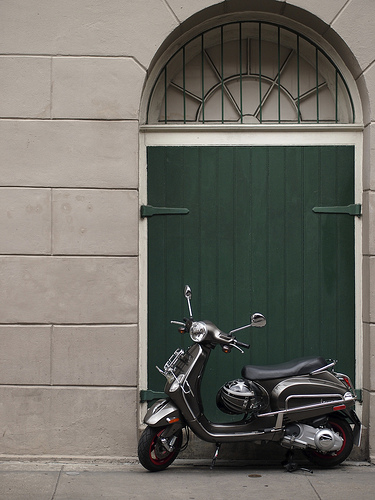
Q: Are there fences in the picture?
A: No, there are no fences.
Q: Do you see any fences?
A: No, there are no fences.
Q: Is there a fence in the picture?
A: No, there are no fences.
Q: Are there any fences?
A: No, there are no fences.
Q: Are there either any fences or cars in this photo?
A: No, there are no fences or cars.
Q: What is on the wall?
A: The bricks are on the wall.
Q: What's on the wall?
A: The bricks are on the wall.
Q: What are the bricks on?
A: The bricks are on the wall.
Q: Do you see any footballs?
A: No, there are no footballs.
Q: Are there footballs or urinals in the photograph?
A: No, there are no footballs or urinals.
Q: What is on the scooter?
A: The seat is on the scooter.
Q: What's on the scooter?
A: The seat is on the scooter.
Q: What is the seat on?
A: The seat is on the scooter.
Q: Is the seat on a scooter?
A: Yes, the seat is on a scooter.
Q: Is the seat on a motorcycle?
A: No, the seat is on a scooter.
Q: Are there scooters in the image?
A: Yes, there is a scooter.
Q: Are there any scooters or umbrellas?
A: Yes, there is a scooter.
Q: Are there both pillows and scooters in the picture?
A: No, there is a scooter but no pillows.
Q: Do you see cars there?
A: No, there are no cars.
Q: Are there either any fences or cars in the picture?
A: No, there are no cars or fences.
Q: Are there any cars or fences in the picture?
A: No, there are no cars or fences.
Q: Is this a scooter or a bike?
A: This is a scooter.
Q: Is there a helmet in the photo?
A: Yes, there is a helmet.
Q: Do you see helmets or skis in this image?
A: Yes, there is a helmet.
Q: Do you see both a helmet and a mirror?
A: Yes, there are both a helmet and a mirror.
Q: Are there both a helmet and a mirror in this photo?
A: Yes, there are both a helmet and a mirror.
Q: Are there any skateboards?
A: No, there are no skateboards.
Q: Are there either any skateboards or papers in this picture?
A: No, there are no skateboards or papers.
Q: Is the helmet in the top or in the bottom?
A: The helmet is in the bottom of the image.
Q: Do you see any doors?
A: Yes, there is a door.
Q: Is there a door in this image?
A: Yes, there is a door.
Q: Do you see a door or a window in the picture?
A: Yes, there is a door.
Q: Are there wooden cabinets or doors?
A: Yes, there is a wood door.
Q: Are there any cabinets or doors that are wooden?
A: Yes, the door is wooden.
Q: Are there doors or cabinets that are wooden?
A: Yes, the door is wooden.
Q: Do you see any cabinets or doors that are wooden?
A: Yes, the door is wooden.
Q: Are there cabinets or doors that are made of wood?
A: Yes, the door is made of wood.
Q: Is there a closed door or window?
A: Yes, there is a closed door.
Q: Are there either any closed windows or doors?
A: Yes, there is a closed door.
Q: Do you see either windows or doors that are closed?
A: Yes, the door is closed.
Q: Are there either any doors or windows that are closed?
A: Yes, the door is closed.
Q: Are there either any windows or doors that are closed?
A: Yes, the door is closed.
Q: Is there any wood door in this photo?
A: Yes, there is a wood door.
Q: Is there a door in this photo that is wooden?
A: Yes, there is a door that is wooden.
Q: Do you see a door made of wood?
A: Yes, there is a door that is made of wood.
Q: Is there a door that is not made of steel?
A: Yes, there is a door that is made of wood.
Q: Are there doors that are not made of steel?
A: Yes, there is a door that is made of wood.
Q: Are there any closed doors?
A: Yes, there is a closed door.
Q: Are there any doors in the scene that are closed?
A: Yes, there is a door that is closed.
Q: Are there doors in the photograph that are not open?
A: Yes, there is an closed door.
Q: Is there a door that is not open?
A: Yes, there is an closed door.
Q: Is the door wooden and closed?
A: Yes, the door is wooden and closed.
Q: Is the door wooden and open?
A: No, the door is wooden but closed.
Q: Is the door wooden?
A: Yes, the door is wooden.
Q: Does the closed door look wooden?
A: Yes, the door is wooden.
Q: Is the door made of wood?
A: Yes, the door is made of wood.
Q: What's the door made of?
A: The door is made of wood.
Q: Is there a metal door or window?
A: No, there is a door but it is wooden.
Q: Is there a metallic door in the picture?
A: No, there is a door but it is wooden.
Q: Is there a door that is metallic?
A: No, there is a door but it is wooden.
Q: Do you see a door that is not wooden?
A: No, there is a door but it is wooden.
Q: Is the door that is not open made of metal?
A: No, the door is made of wood.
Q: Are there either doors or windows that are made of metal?
A: No, there is a door but it is made of wood.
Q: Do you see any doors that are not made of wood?
A: No, there is a door but it is made of wood.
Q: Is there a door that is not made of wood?
A: No, there is a door but it is made of wood.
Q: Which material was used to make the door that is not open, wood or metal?
A: The door is made of wood.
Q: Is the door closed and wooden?
A: Yes, the door is closed and wooden.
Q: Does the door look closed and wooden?
A: Yes, the door is closed and wooden.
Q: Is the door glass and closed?
A: No, the door is closed but wooden.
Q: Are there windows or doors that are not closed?
A: No, there is a door but it is closed.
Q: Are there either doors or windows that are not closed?
A: No, there is a door but it is closed.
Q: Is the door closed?
A: Yes, the door is closed.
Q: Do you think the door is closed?
A: Yes, the door is closed.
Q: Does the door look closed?
A: Yes, the door is closed.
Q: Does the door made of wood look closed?
A: Yes, the door is closed.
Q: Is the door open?
A: No, the door is closed.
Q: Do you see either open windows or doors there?
A: No, there is a door but it is closed.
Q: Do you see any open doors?
A: No, there is a door but it is closed.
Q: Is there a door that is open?
A: No, there is a door but it is closed.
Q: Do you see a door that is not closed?
A: No, there is a door but it is closed.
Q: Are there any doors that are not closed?
A: No, there is a door but it is closed.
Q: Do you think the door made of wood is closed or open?
A: The door is closed.